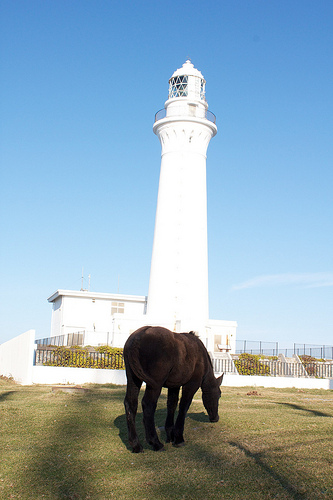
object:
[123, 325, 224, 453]
horse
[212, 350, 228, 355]
stairs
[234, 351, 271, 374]
bush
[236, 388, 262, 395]
poop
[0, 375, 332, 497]
grass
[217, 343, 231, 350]
plaque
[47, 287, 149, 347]
house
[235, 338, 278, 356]
fence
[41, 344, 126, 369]
bushes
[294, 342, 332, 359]
fence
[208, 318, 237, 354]
house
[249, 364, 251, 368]
leaves